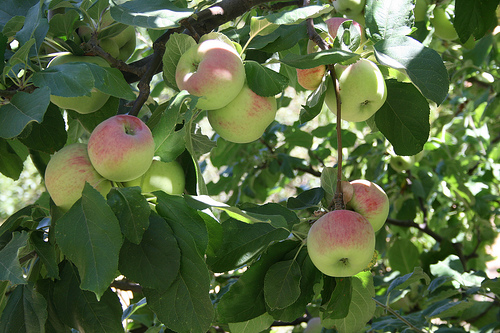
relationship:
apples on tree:
[189, 52, 286, 148] [97, 18, 417, 307]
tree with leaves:
[97, 18, 417, 307] [29, 57, 109, 120]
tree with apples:
[97, 18, 417, 307] [189, 52, 286, 148]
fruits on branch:
[158, 53, 317, 197] [109, 31, 199, 88]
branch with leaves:
[109, 31, 199, 88] [29, 57, 109, 120]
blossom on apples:
[230, 26, 291, 97] [189, 52, 286, 148]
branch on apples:
[109, 31, 199, 88] [189, 52, 286, 148]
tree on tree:
[0, 0, 500, 333] [97, 18, 417, 307]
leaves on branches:
[29, 57, 109, 120] [83, 18, 233, 184]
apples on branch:
[189, 52, 286, 148] [5, 2, 303, 119]